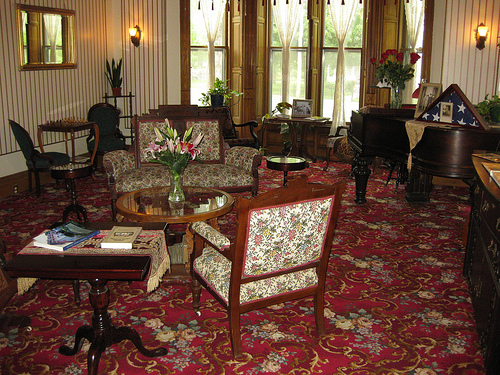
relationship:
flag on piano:
[429, 88, 492, 128] [357, 115, 475, 194]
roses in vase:
[371, 51, 434, 79] [378, 80, 424, 113]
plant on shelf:
[94, 55, 156, 113] [107, 91, 153, 140]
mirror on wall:
[20, 9, 79, 67] [4, 13, 93, 117]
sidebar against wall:
[55, 114, 137, 182] [4, 13, 93, 117]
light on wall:
[97, 16, 184, 75] [4, 13, 93, 117]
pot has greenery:
[107, 85, 139, 104] [108, 60, 146, 78]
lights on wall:
[97, 20, 179, 66] [4, 13, 93, 117]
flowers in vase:
[166, 125, 214, 159] [378, 80, 424, 113]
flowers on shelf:
[166, 125, 214, 159] [107, 91, 153, 140]